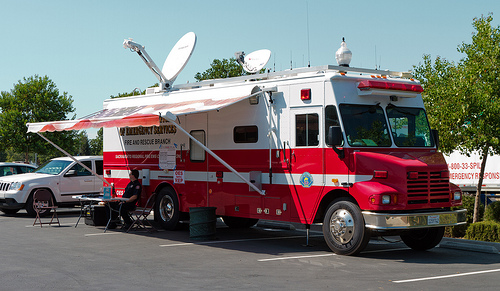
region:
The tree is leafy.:
[424, 46, 497, 128]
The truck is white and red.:
[96, 75, 458, 264]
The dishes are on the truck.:
[101, 15, 314, 102]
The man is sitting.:
[89, 159, 163, 243]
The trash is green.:
[178, 191, 204, 253]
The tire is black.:
[300, 190, 380, 264]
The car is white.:
[15, 140, 115, 217]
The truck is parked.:
[49, 74, 463, 280]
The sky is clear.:
[8, 7, 121, 78]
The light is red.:
[348, 70, 446, 104]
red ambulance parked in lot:
[13, 22, 469, 254]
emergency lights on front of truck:
[350, 75, 430, 100]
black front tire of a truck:
[317, 196, 375, 251]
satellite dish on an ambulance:
[110, 29, 213, 91]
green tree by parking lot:
[429, 7, 499, 240]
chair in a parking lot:
[25, 181, 70, 229]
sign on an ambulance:
[168, 167, 193, 185]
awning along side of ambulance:
[19, 87, 274, 137]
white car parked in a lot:
[0, 147, 109, 211]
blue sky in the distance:
[16, 7, 440, 30]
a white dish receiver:
[129, 27, 200, 104]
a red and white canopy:
[28, 95, 274, 189]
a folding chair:
[28, 185, 61, 226]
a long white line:
[392, 259, 498, 286]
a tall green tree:
[421, 14, 498, 236]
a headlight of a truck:
[379, 194, 398, 202]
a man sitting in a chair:
[105, 166, 141, 233]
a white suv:
[0, 154, 102, 215]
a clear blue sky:
[0, 0, 498, 120]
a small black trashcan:
[186, 202, 218, 240]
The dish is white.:
[115, 31, 207, 92]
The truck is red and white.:
[73, 61, 432, 252]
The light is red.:
[340, 45, 437, 113]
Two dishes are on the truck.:
[85, 15, 297, 79]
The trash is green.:
[170, 190, 220, 256]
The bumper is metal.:
[365, 200, 477, 238]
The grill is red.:
[383, 143, 456, 233]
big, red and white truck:
[28, 29, 464, 253]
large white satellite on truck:
[120, 31, 199, 86]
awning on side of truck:
[25, 85, 281, 191]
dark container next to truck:
[181, 205, 216, 235]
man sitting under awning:
[106, 168, 141, 226]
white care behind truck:
[0, 156, 105, 213]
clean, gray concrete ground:
[0, 208, 499, 288]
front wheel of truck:
[323, 198, 363, 254]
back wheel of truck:
[155, 191, 179, 226]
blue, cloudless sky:
[1, 0, 498, 139]